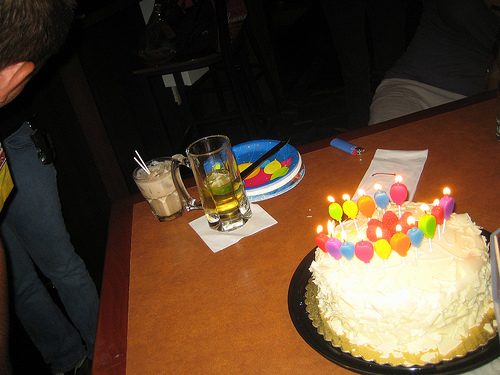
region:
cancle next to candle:
[325, 196, 340, 227]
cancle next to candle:
[340, 195, 355, 225]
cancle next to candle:
[357, 195, 373, 217]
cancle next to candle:
[372, 190, 387, 210]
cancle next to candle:
[390, 180, 407, 215]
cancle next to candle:
[315, 231, 327, 256]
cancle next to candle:
[325, 235, 340, 265]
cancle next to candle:
[340, 240, 352, 260]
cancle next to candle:
[355, 240, 373, 262]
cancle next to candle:
[373, 236, 393, 258]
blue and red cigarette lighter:
[331, 133, 369, 163]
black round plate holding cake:
[284, 255, 464, 373]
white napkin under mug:
[178, 200, 272, 245]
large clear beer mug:
[164, 130, 256, 225]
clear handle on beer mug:
[160, 153, 205, 216]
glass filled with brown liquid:
[125, 160, 190, 218]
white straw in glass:
[126, 141, 155, 181]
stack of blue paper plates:
[208, 132, 323, 208]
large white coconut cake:
[303, 182, 490, 335]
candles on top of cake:
[321, 174, 471, 259]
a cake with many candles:
[301, 173, 498, 363]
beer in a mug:
[171, 134, 251, 233]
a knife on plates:
[238, 136, 291, 180]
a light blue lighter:
[327, 136, 364, 156]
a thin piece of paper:
[350, 149, 428, 202]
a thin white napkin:
[190, 207, 277, 249]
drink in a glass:
[130, 148, 182, 219]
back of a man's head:
[0, 0, 55, 120]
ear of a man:
[4, 61, 38, 105]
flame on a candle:
[313, 223, 323, 235]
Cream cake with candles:
[294, 175, 487, 363]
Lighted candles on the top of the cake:
[294, 178, 464, 259]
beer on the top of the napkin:
[169, 128, 262, 255]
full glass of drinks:
[113, 130, 184, 219]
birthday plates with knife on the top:
[219, 128, 301, 200]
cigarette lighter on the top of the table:
[321, 134, 365, 166]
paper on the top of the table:
[360, 140, 425, 203]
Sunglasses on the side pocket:
[19, 122, 54, 172]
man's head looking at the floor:
[2, 0, 45, 110]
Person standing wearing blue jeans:
[0, 108, 101, 350]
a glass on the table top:
[123, 147, 188, 225]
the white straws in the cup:
[128, 147, 155, 174]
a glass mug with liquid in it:
[171, 126, 256, 231]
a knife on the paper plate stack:
[240, 133, 299, 193]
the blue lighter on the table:
[325, 126, 366, 164]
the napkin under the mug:
[179, 218, 284, 250]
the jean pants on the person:
[0, 114, 97, 356]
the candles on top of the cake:
[308, 167, 473, 254]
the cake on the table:
[292, 181, 492, 373]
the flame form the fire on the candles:
[320, 173, 412, 205]